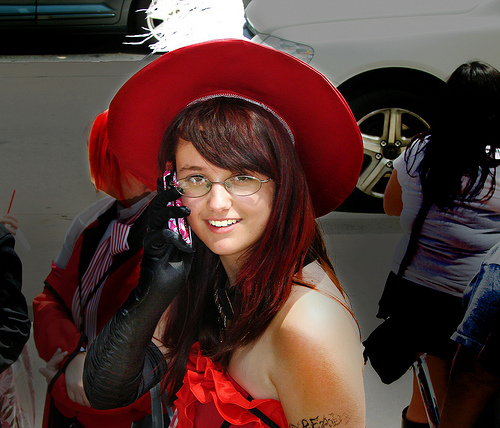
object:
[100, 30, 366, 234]
hat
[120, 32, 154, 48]
feathers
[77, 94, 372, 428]
girl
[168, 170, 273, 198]
eyeglasses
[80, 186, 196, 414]
glove